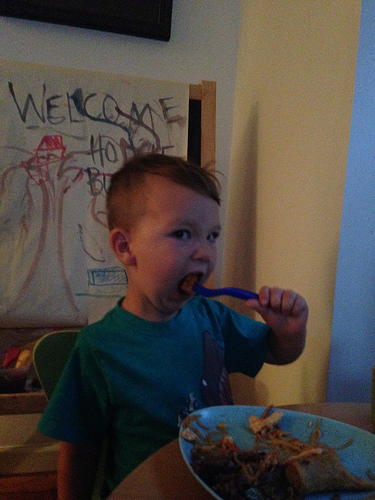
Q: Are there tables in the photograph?
A: Yes, there is a table.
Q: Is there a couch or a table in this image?
A: Yes, there is a table.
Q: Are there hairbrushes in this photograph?
A: No, there are no hairbrushes.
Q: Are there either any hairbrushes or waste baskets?
A: No, there are no hairbrushes or waste baskets.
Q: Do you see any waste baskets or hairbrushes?
A: No, there are no hairbrushes or waste baskets.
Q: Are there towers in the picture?
A: No, there are no towers.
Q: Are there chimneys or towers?
A: No, there are no towers or chimneys.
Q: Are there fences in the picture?
A: No, there are no fences.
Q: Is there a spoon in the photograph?
A: Yes, there is a spoon.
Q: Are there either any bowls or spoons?
A: Yes, there is a spoon.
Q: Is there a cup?
A: No, there are no cups.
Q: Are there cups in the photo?
A: No, there are no cups.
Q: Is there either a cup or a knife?
A: No, there are no cups or knives.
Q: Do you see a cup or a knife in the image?
A: No, there are no cups or knives.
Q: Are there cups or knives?
A: No, there are no cups or knives.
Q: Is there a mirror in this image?
A: No, there are no mirrors.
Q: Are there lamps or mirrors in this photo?
A: No, there are no mirrors or lamps.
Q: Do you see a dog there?
A: No, there are no dogs.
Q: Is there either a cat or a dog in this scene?
A: No, there are no dogs or cats.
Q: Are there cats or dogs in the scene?
A: No, there are no dogs or cats.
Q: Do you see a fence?
A: No, there are no fences.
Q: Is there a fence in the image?
A: No, there are no fences.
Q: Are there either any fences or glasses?
A: No, there are no fences or glasses.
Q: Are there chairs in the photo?
A: Yes, there is a chair.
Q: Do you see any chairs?
A: Yes, there is a chair.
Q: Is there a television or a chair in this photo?
A: Yes, there is a chair.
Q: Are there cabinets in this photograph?
A: No, there are no cabinets.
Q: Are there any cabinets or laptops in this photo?
A: No, there are no cabinets or laptops.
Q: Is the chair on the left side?
A: Yes, the chair is on the left of the image.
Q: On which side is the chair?
A: The chair is on the left of the image.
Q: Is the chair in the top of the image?
A: No, the chair is in the bottom of the image.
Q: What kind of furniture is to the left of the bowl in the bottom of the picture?
A: The piece of furniture is a chair.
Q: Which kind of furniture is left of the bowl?
A: The piece of furniture is a chair.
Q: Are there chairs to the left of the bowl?
A: Yes, there is a chair to the left of the bowl.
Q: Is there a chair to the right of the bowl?
A: No, the chair is to the left of the bowl.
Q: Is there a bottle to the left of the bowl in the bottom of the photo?
A: No, there is a chair to the left of the bowl.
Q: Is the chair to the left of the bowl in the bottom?
A: Yes, the chair is to the left of the bowl.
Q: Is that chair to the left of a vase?
A: No, the chair is to the left of the bowl.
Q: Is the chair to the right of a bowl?
A: No, the chair is to the left of a bowl.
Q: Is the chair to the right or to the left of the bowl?
A: The chair is to the left of the bowl.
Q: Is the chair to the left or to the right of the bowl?
A: The chair is to the left of the bowl.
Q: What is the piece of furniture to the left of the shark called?
A: The piece of furniture is a chair.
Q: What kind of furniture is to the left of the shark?
A: The piece of furniture is a chair.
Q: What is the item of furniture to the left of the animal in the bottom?
A: The piece of furniture is a chair.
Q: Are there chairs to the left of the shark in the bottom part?
A: Yes, there is a chair to the left of the shark.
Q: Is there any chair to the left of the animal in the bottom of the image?
A: Yes, there is a chair to the left of the shark.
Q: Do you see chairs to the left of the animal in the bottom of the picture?
A: Yes, there is a chair to the left of the shark.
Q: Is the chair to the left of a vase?
A: No, the chair is to the left of the shark.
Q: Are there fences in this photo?
A: No, there are no fences.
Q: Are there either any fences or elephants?
A: No, there are no fences or elephants.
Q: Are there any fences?
A: No, there are no fences.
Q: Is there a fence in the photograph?
A: No, there are no fences.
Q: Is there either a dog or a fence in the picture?
A: No, there are no fences or dogs.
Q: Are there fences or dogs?
A: No, there are no fences or dogs.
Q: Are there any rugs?
A: No, there are no rugs.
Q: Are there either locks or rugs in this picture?
A: No, there are no rugs or locks.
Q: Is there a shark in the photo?
A: Yes, there is a shark.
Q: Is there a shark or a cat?
A: Yes, there is a shark.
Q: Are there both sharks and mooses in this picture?
A: No, there is a shark but no mooses.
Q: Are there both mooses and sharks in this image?
A: No, there is a shark but no mooses.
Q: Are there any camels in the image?
A: No, there are no camels.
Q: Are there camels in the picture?
A: No, there are no camels.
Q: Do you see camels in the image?
A: No, there are no camels.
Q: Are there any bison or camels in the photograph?
A: No, there are no camels or bison.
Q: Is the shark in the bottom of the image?
A: Yes, the shark is in the bottom of the image.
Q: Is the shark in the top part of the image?
A: No, the shark is in the bottom of the image.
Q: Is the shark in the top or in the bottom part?
A: The shark is in the bottom of the image.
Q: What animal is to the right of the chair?
A: The animal is a shark.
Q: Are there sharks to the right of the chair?
A: Yes, there is a shark to the right of the chair.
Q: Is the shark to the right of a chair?
A: Yes, the shark is to the right of a chair.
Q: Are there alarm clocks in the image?
A: No, there are no alarm clocks.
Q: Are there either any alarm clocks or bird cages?
A: No, there are no alarm clocks or bird cages.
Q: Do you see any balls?
A: No, there are no balls.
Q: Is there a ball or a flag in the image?
A: No, there are no balls or flags.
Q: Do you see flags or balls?
A: No, there are no balls or flags.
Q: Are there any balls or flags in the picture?
A: No, there are no balls or flags.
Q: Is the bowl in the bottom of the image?
A: Yes, the bowl is in the bottom of the image.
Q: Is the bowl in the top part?
A: No, the bowl is in the bottom of the image.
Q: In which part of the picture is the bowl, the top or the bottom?
A: The bowl is in the bottom of the image.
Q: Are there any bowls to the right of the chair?
A: Yes, there is a bowl to the right of the chair.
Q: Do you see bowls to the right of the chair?
A: Yes, there is a bowl to the right of the chair.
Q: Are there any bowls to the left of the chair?
A: No, the bowl is to the right of the chair.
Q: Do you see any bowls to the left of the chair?
A: No, the bowl is to the right of the chair.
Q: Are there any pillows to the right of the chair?
A: No, there is a bowl to the right of the chair.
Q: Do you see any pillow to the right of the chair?
A: No, there is a bowl to the right of the chair.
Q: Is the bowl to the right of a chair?
A: Yes, the bowl is to the right of a chair.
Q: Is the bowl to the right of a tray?
A: No, the bowl is to the right of a chair.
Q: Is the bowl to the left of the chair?
A: No, the bowl is to the right of the chair.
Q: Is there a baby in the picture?
A: Yes, there is a baby.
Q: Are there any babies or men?
A: Yes, there is a baby.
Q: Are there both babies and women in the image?
A: No, there is a baby but no women.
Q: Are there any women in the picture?
A: No, there are no women.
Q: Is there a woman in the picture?
A: No, there are no women.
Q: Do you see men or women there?
A: No, there are no women or men.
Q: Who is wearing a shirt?
A: The baby is wearing a shirt.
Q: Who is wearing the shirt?
A: The baby is wearing a shirt.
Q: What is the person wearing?
A: The baby is wearing a shirt.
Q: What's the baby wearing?
A: The baby is wearing a shirt.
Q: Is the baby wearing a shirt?
A: Yes, the baby is wearing a shirt.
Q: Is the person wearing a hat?
A: No, the baby is wearing a shirt.